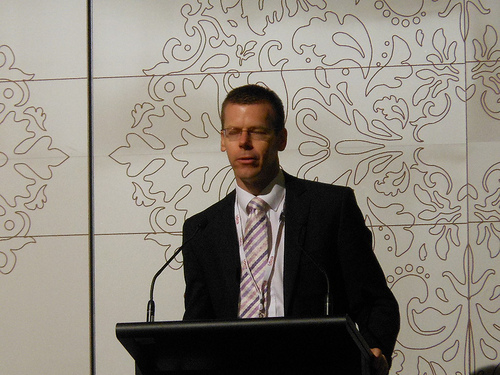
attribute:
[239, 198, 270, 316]
tie — striped, light, colorful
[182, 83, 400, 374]
man — speaking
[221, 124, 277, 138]
glasses — clear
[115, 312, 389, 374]
podium — black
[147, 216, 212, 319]
microphone — small, black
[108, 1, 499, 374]
artwork — brown, gray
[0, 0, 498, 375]
wall — white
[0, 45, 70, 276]
artwork — brown, gray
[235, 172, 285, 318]
shirt — white, dress shirt, button down, smart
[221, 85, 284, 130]
hair — short, brown, brrown, dark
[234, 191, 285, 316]
lanyard — white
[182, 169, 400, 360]
jacket — dark, suit jacket, black, smart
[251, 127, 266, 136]
eye — closed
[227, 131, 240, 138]
eye — closed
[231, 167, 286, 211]
collar — white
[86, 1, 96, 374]
separation — black